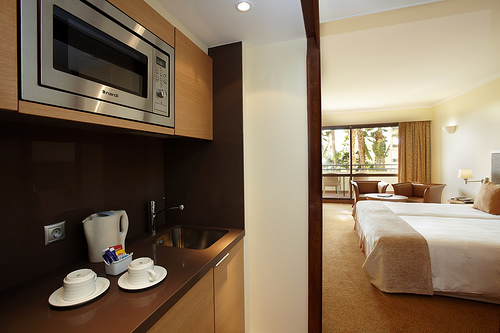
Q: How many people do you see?
A: 0.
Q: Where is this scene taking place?
A: Hotel room.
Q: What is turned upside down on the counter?
A: Coffee cups.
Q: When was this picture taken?
A: Daytime.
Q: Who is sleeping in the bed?
A: No one.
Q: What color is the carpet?
A: Light brown.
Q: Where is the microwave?
A: Upper cabinet.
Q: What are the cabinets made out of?
A: Wood.